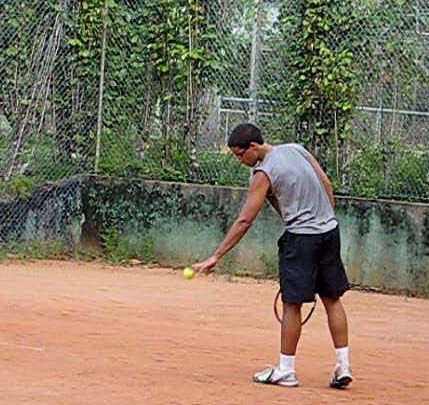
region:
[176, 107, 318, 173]
man with short hair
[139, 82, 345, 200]
man with short dark hair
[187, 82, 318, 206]
man wearing dark glasses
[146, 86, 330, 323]
man bouncing a tennis ball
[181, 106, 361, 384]
man holding a tennis racquet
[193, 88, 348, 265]
man wearing a gray pullover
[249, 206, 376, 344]
man wearing blue shorts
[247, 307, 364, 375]
man wearing pair of white socks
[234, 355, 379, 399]
man wearign pair of white tennis shoes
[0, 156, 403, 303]
block wall behind tennis court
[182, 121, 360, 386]
a young man getting ready to serve a tennis ball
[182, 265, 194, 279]
a yellow tennis ball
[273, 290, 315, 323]
the head of a tennis racket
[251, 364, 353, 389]
tennis shoes on the young man's feet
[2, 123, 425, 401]
tennis player on the back end of a tennis court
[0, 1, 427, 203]
a tall metal fence surrounding the tennis court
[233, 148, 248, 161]
eyeglasses on the boy's face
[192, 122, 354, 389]
a gray t-shirt on the tennis player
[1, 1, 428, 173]
trees behind the fence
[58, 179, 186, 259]
stone retaining wall holding a metal fence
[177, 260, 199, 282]
A green tennis ball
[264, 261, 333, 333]
A tennis racket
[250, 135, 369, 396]
The man holds a tennis racket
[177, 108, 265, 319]
The man dribbles a tennis ball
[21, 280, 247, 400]
A dirt court underneath the man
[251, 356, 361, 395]
White shoes on the man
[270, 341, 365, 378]
The man wears white socks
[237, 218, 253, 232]
The man's elbow is wrinkly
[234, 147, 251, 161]
Glasses on the man's face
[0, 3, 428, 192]
A chain link fence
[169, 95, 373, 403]
Man playing tennis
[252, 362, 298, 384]
White men's tennis shoes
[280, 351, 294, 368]
White men's tube socks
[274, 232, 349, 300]
Black men's shorts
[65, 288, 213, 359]
Clay playing surface on tennis court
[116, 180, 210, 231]
Algae stains on concrete wall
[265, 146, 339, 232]
Men's grey tank top shirt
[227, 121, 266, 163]
Short black haircut on man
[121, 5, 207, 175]
Vegetation behind a chain link fence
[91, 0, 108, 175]
Metal post holding chain link fence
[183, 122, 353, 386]
black man bouncing tennis ball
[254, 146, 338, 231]
grey sleeveless t-shirt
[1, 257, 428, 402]
red clay tennis court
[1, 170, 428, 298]
low concrete wall with algae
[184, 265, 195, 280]
yellow tennis ball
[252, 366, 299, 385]
left tennis shoe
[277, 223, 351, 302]
dark shorts on man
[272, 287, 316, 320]
tennis racket held at knee level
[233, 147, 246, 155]
eyeglasses on man's face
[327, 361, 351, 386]
man's left tennis shoe